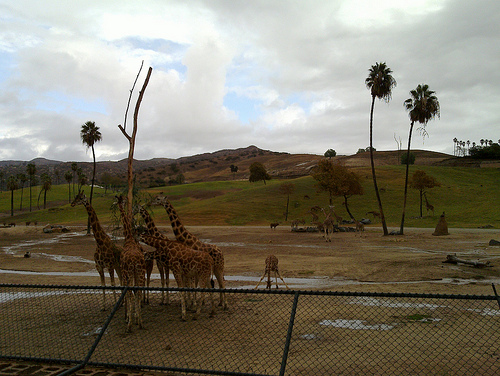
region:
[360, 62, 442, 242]
two tall palm trees beside one another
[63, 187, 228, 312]
a group of 5 giraffes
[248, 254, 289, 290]
one young giraffe drinking water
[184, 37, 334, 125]
grey clouds in the sky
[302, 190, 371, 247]
a few giraffes in the distance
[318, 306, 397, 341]
a water puddle behind a metal fence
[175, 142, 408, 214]
brown and green hills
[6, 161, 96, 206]
a row of palm trees to the left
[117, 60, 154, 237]
a tall dead tree trunk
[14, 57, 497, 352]
several giraffes in an enclosure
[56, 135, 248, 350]
these are giraffes in a zoo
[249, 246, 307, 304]
a small giraffe drinking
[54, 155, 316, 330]
there are five giraffes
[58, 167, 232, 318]
there are four giraffes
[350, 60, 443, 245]
there are two palm trees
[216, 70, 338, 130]
the sky is cloudy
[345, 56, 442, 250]
the trees are palms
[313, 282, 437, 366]
the fence is black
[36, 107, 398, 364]
a herd of animals in a zoo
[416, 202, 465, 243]
this is a termite mound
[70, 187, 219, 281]
Group of giraffes standing together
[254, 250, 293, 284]
Giraffe with spread legs drinking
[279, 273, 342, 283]
Small pool of water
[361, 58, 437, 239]
Pair of tall trees with all leaves at the top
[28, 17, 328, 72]
Cloudy sky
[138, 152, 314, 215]
Rolling hills of green and gold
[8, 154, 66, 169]
Distant mountains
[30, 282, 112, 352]
Fence that has fallen down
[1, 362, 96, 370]
Bricks next to a fence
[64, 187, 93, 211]
Face of a giraffe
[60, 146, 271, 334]
giraffes clustered around feeding basket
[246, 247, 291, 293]
young giraffe with legs splayed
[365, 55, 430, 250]
two tall palm trees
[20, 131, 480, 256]
gentle slopes covering terrain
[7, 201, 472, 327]
streams and puddles of water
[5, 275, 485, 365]
metal fence leaning toward animals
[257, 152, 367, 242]
smaller animals gathered under tree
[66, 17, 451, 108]
grey clouds under blue skies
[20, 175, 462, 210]
grass growing over hills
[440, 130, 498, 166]
row of trees on top of hill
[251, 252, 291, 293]
unbalanced baby giraffe trying to drink water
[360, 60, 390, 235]
tallest of the palm trees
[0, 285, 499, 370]
chainlink fence that's leaning hard for the giraffes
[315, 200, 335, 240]
adult kangaroo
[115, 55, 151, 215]
tree that has a new purpose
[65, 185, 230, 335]
bunch of giraffes standing around the feeder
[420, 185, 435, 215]
adult giraffe that is off in the distance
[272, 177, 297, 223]
tiniest of the palm trees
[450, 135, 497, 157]
bunch of palm trees way off in the distance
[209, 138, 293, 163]
small mountain off in the distance